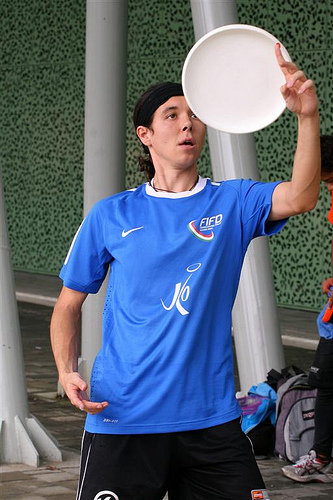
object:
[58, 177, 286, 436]
shirt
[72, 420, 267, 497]
shorts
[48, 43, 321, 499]
man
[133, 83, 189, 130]
head band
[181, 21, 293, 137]
frisbee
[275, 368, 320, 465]
backpack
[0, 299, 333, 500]
ground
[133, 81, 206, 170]
head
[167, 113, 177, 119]
eye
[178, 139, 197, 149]
mouth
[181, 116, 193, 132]
nose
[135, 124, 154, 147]
ear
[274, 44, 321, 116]
hand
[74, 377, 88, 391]
thumb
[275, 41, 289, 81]
finger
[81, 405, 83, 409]
fingernail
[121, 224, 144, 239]
logo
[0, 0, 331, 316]
wall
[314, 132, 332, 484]
person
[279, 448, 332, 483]
shoe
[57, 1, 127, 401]
pole